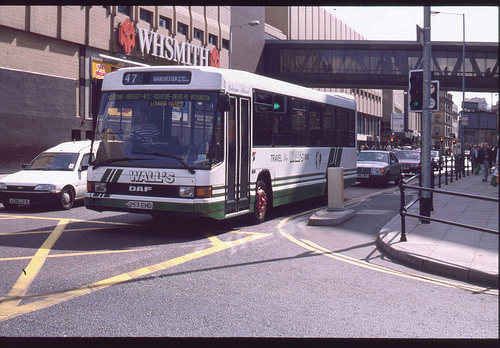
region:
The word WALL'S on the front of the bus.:
[124, 166, 181, 183]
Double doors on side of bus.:
[230, 91, 252, 209]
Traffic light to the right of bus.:
[409, 67, 422, 115]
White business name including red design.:
[113, 16, 230, 64]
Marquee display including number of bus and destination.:
[122, 71, 193, 84]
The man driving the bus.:
[117, 103, 164, 151]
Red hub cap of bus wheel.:
[257, 181, 270, 223]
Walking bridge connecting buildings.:
[263, 32, 498, 95]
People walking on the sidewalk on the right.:
[466, 136, 499, 183]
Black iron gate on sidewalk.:
[396, 171, 499, 256]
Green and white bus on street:
[63, 64, 391, 236]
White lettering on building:
[108, 16, 235, 74]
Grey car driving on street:
[333, 125, 415, 196]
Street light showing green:
[388, 52, 441, 135]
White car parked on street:
[0, 111, 135, 231]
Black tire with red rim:
[227, 158, 286, 247]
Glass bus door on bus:
[215, 83, 260, 228]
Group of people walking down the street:
[462, 128, 495, 188]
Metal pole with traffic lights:
[402, 1, 439, 231]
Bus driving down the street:
[78, 68, 393, 229]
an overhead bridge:
[252, 27, 498, 99]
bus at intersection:
[84, 63, 357, 233]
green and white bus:
[81, 58, 357, 234]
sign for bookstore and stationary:
[116, 18, 224, 72]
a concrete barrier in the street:
[299, 161, 358, 233]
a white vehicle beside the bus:
[0, 132, 110, 210]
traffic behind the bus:
[356, 147, 448, 186]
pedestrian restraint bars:
[387, 171, 497, 256]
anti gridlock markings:
[0, 212, 274, 320]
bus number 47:
[82, 58, 230, 220]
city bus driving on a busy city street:
[72, 55, 363, 227]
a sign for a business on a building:
[106, 14, 223, 69]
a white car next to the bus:
[0, 140, 104, 210]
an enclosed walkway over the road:
[258, 28, 497, 98]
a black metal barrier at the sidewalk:
[396, 167, 498, 259]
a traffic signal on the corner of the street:
[408, 44, 443, 209]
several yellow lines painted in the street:
[14, 222, 231, 319]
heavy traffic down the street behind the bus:
[363, 134, 443, 182]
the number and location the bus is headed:
[118, 71, 195, 86]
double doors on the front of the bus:
[224, 94, 257, 207]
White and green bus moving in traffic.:
[76, 56, 361, 223]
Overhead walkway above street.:
[271, 34, 495, 101]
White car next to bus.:
[1, 131, 91, 218]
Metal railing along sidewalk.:
[392, 169, 498, 246]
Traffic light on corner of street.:
[405, 32, 447, 227]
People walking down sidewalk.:
[466, 135, 497, 185]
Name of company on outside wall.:
[111, 14, 229, 72]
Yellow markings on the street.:
[11, 226, 222, 327]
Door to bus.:
[221, 88, 258, 221]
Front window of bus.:
[87, 85, 235, 171]